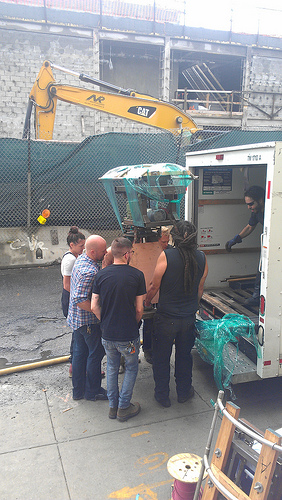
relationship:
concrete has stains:
[108, 396, 184, 475] [73, 400, 187, 499]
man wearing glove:
[223, 181, 271, 251] [219, 232, 251, 269]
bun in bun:
[66, 224, 86, 248] [56, 212, 97, 248]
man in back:
[223, 181, 271, 251] [165, 136, 281, 288]